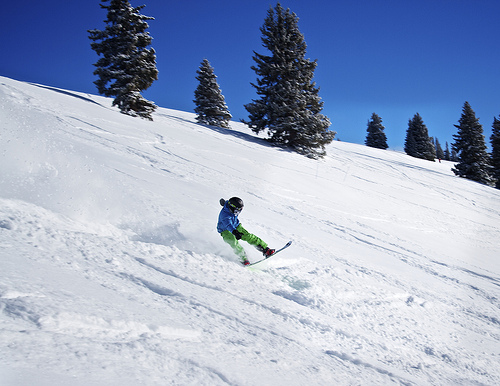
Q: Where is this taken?
A: A ski slope.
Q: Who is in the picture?
A: A snowboarder.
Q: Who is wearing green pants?
A: The snowboarder.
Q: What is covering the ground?
A: Snow.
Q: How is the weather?
A: Sunny.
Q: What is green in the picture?
A: Trees.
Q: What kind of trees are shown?
A: Evergreen.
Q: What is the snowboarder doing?
A: Snowboarding.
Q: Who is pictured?
A: Snow boarder.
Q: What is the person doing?
A: Snowboarding.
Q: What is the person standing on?
A: Snowboard.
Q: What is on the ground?
A: Snow.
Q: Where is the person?
A: A hill.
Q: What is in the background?
A: Trees.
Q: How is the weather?
A: Clear.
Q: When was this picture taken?
A: During day hours.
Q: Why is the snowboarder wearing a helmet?
A: Protection.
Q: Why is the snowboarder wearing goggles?
A: Protection.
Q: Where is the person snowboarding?
A: Downhill.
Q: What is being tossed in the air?
A: Snow.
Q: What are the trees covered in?
A: Snow.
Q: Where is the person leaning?
A: Backwards.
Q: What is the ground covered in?
A: Snow.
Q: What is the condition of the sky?
A: Clear.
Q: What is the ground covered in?
A: Snow.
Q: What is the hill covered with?
A: Snow.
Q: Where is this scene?
A: Ski slope.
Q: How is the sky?
A: Clear.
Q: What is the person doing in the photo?
A: Skiing.